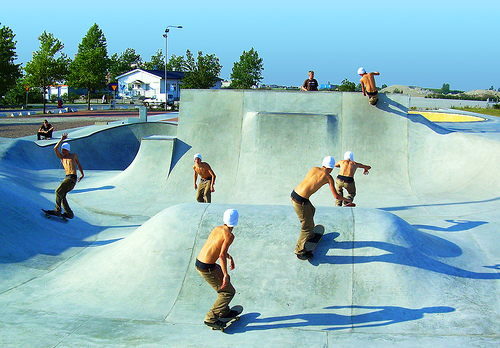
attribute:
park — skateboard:
[8, 11, 493, 338]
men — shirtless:
[40, 136, 405, 296]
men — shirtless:
[45, 128, 382, 293]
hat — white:
[220, 201, 242, 229]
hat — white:
[311, 151, 335, 168]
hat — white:
[340, 145, 360, 163]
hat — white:
[188, 146, 202, 166]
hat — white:
[51, 136, 71, 155]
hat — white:
[222, 209, 240, 233]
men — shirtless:
[38, 129, 404, 278]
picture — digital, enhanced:
[3, 5, 498, 342]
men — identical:
[22, 119, 378, 302]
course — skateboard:
[22, 87, 497, 339]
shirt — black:
[36, 120, 56, 133]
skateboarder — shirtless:
[284, 158, 344, 267]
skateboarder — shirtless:
[181, 211, 271, 336]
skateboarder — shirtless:
[180, 148, 223, 213]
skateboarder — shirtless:
[50, 132, 75, 224]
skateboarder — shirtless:
[325, 146, 366, 209]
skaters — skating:
[47, 73, 475, 342]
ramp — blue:
[189, 192, 326, 323]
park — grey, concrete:
[180, 174, 420, 284]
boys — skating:
[10, 131, 363, 308]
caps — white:
[47, 153, 430, 236]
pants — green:
[178, 271, 256, 311]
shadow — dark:
[272, 293, 461, 318]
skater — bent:
[194, 181, 267, 329]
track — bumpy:
[68, 91, 408, 286]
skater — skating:
[60, 142, 90, 202]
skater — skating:
[20, 83, 85, 224]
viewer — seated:
[12, 109, 70, 127]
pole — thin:
[145, 65, 173, 123]